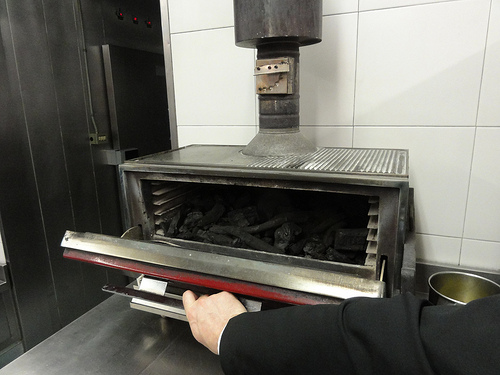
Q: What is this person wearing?
A: A dark suit coat.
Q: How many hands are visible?
A: One.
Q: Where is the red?
A: On the top of the oven door.